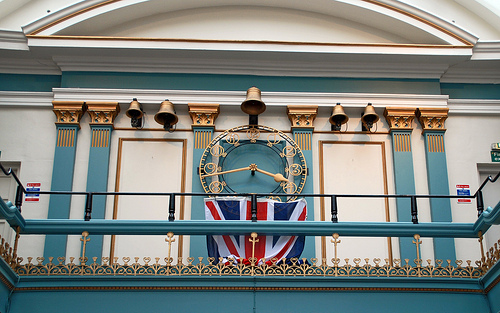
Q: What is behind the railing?
A: A flag.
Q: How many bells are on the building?
A: Five.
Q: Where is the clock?
A: On the front of building.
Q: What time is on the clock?
A: 3:43.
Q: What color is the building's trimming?
A: Blue.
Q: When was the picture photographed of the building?
A: Daytime.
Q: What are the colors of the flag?
A: Red, white, and blue.